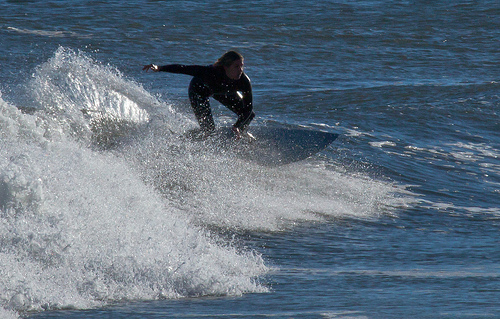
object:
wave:
[0, 47, 388, 303]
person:
[143, 51, 258, 142]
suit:
[157, 63, 256, 131]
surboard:
[188, 127, 340, 169]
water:
[0, 1, 499, 316]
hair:
[212, 50, 242, 71]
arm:
[160, 64, 211, 76]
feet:
[233, 130, 257, 137]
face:
[224, 60, 244, 79]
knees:
[200, 114, 212, 124]